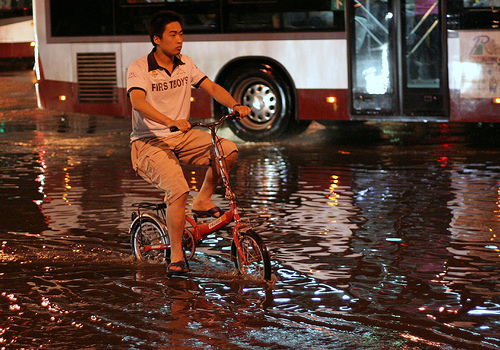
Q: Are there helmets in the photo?
A: No, there are no helmets.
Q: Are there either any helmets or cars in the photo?
A: No, there are no helmets or cars.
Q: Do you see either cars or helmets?
A: No, there are no helmets or cars.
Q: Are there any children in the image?
A: No, there are no children.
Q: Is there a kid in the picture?
A: No, there are no children.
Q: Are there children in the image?
A: No, there are no children.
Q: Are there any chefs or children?
A: No, there are no children or chefs.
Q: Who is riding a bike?
A: The man is riding a bike.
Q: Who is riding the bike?
A: The man is riding a bike.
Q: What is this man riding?
A: The man is riding a bike.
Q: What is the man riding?
A: The man is riding a bike.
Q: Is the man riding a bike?
A: Yes, the man is riding a bike.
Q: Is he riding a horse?
A: No, the man is riding a bike.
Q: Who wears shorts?
A: The man wears shorts.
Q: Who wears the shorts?
A: The man wears shorts.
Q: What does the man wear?
A: The man wears shorts.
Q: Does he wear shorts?
A: Yes, the man wears shorts.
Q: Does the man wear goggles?
A: No, the man wears shorts.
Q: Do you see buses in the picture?
A: Yes, there is a bus.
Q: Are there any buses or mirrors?
A: Yes, there is a bus.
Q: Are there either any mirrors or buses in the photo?
A: Yes, there is a bus.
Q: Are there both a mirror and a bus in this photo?
A: No, there is a bus but no mirrors.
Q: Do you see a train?
A: No, there are no trains.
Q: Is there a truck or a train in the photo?
A: No, there are no trains or trucks.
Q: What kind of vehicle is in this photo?
A: The vehicle is a bus.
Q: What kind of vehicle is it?
A: The vehicle is a bus.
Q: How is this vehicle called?
A: This is a bus.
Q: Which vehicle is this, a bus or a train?
A: This is a bus.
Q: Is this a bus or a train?
A: This is a bus.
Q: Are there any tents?
A: No, there are no tents.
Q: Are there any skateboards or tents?
A: No, there are no tents or skateboards.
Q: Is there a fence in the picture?
A: No, there are no fences.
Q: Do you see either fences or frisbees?
A: No, there are no fences or frisbees.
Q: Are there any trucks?
A: No, there are no trucks.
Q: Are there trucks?
A: No, there are no trucks.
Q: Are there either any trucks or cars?
A: No, there are no trucks or cars.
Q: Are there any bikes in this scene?
A: Yes, there is a bike.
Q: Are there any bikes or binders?
A: Yes, there is a bike.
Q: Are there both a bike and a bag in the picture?
A: No, there is a bike but no bags.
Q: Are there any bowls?
A: No, there are no bowls.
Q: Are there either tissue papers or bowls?
A: No, there are no bowls or tissue papers.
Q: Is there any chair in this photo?
A: No, there are no chairs.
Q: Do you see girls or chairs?
A: No, there are no chairs or girls.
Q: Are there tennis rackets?
A: No, there are no tennis rackets.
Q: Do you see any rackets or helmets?
A: No, there are no rackets or helmets.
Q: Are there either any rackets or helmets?
A: No, there are no rackets or helmets.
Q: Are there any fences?
A: No, there are no fences.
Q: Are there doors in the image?
A: Yes, there are doors.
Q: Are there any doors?
A: Yes, there are doors.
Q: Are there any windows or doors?
A: Yes, there are doors.